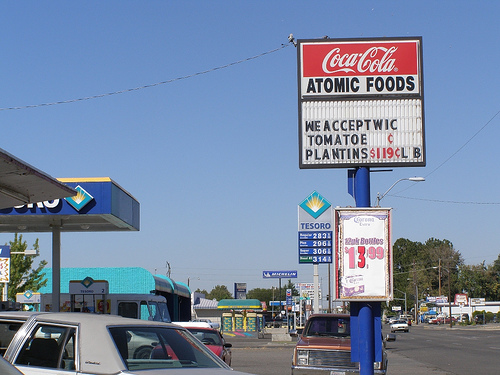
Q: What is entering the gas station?
A: A car.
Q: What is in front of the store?
A: A sign.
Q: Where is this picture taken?
A: A gas station.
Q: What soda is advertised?
A: Coca Cola.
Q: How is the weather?
A: Clear.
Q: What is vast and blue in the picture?
A: The sky.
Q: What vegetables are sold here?
A: Tomatoes and plantains.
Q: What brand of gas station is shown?
A: Tresorio.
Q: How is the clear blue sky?
A: Cloudless.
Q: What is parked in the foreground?
A: A car.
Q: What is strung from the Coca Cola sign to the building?
A: Flags.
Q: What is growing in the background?
A: Trees.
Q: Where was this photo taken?
A: Near a gas station.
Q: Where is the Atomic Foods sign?
A: On the pole in front of the camera.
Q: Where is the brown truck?
A: Behind the pole of the sign.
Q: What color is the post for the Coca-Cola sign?
A: Blue.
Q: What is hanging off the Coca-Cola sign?
A: A power line.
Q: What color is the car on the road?
A: White.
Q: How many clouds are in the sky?
A: None.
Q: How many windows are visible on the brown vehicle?
A: One.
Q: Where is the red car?
A: Behind the grey one.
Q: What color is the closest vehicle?
A: Grey.